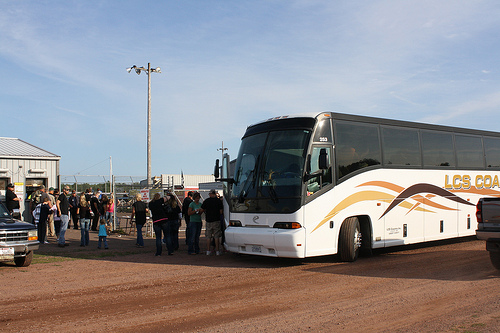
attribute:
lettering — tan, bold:
[404, 159, 491, 201]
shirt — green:
[189, 200, 196, 220]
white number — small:
[317, 136, 329, 144]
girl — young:
[94, 216, 106, 244]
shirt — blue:
[96, 221, 108, 237]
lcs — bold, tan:
[443, 170, 474, 192]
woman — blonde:
[134, 190, 149, 251]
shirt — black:
[127, 202, 150, 219]